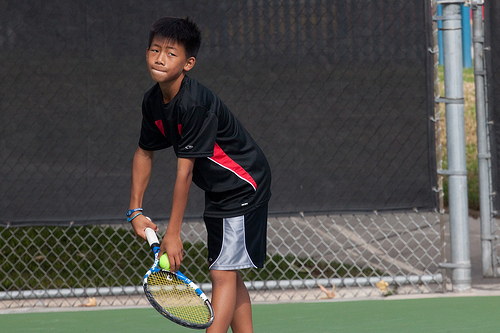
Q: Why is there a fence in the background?
A: Enclose the tennis court.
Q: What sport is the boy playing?
A: Tennis.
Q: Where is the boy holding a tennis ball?
A: On racket.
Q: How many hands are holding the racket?
A: One.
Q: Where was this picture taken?
A: Tennis court.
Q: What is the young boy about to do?
A: Serve ball.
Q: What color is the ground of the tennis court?
A: Green.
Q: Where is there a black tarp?
A: Hanging on fence.